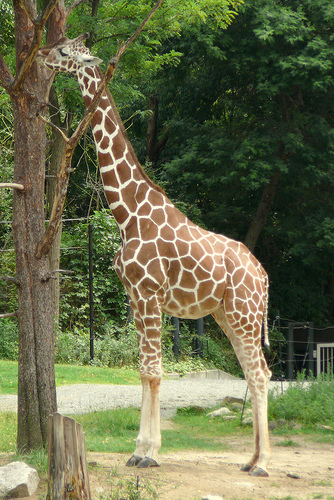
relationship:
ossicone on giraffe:
[72, 28, 102, 51] [34, 30, 271, 479]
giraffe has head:
[34, 30, 271, 479] [29, 28, 104, 86]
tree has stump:
[6, 59, 112, 455] [43, 408, 92, 498]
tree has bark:
[0, 0, 164, 458] [14, 0, 80, 451]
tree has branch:
[0, 0, 164, 458] [234, 64, 311, 254]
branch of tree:
[33, 0, 161, 259] [209, 21, 293, 124]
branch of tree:
[35, 0, 162, 258] [1, 1, 242, 453]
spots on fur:
[155, 241, 254, 305] [112, 174, 275, 407]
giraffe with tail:
[36, 34, 281, 448] [257, 271, 274, 339]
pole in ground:
[78, 203, 100, 370] [66, 348, 112, 397]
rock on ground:
[6, 453, 58, 498] [193, 452, 234, 497]